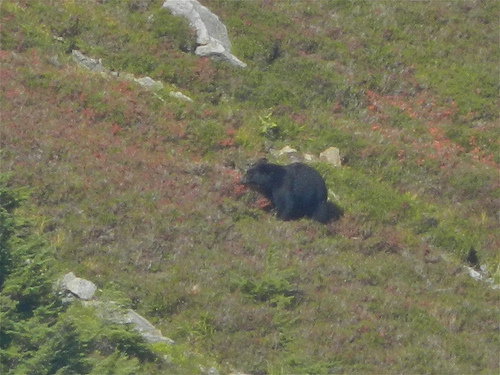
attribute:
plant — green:
[298, 141, 442, 293]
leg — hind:
[304, 194, 352, 234]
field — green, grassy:
[0, 0, 499, 372]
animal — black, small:
[237, 156, 348, 226]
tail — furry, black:
[312, 197, 347, 223]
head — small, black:
[232, 152, 282, 187]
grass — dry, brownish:
[2, 43, 499, 373]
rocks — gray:
[64, 44, 196, 104]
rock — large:
[45, 264, 177, 354]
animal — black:
[234, 156, 343, 220]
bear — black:
[240, 155, 351, 223]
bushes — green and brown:
[2, 182, 227, 372]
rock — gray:
[317, 141, 343, 168]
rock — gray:
[301, 150, 320, 161]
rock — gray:
[58, 268, 175, 354]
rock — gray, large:
[69, 47, 191, 106]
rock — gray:
[317, 142, 346, 162]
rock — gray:
[270, 142, 321, 160]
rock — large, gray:
[156, 0, 254, 70]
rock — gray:
[53, 267, 173, 349]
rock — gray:
[66, 43, 196, 103]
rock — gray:
[154, 0, 247, 65]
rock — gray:
[53, 268, 178, 362]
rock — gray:
[268, 142, 321, 169]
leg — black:
[307, 207, 367, 219]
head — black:
[242, 165, 275, 194]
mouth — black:
[236, 169, 260, 192]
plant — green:
[417, 181, 434, 206]